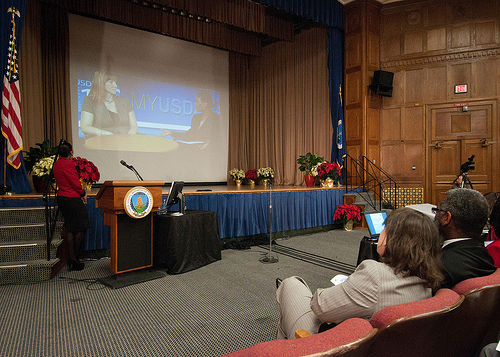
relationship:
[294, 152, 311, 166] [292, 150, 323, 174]
leaf on plant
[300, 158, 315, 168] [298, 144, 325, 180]
leaf on plant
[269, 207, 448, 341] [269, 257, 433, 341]
woman wearing suit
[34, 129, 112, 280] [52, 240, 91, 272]
woman wearing boots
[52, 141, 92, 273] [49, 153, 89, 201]
woman wearing shirt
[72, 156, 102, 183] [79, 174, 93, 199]
flowers in vase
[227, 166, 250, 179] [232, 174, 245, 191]
flowers in pot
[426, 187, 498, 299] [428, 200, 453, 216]
man wearing glasses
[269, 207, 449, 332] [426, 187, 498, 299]
woman sitting next to man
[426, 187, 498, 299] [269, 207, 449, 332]
man sitting next to woman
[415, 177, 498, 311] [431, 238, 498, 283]
man wearing suit jacket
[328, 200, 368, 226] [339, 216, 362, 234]
flowers in vase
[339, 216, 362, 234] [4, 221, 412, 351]
vase on floor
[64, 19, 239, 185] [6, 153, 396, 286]
screen on stage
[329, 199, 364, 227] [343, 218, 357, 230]
flowers in vase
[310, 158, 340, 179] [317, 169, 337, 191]
flowers in pot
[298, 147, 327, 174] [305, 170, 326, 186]
flowers in pot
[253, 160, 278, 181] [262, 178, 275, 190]
flowers in pot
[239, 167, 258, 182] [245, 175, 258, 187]
flowers in pot